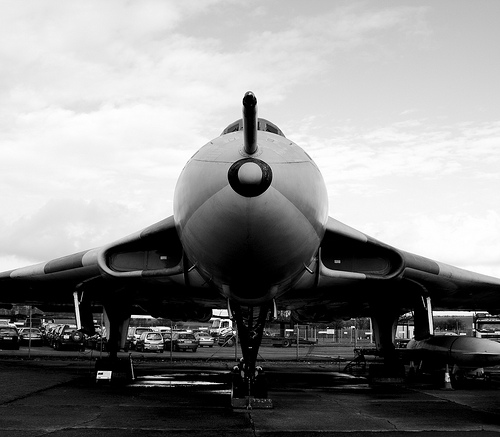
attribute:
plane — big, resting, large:
[0, 116, 499, 363]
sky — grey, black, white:
[30, 17, 486, 80]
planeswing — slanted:
[341, 220, 490, 313]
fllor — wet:
[153, 369, 216, 404]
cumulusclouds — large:
[50, 9, 225, 102]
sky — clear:
[358, 44, 488, 97]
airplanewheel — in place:
[233, 376, 284, 408]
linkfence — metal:
[160, 329, 220, 363]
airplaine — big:
[0, 87, 499, 431]